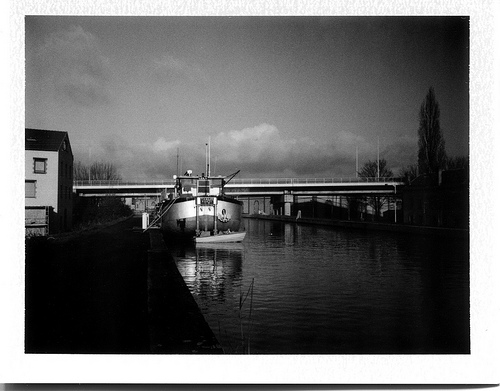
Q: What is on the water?
A: A boat.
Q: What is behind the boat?
A: A bridge.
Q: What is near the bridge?
A: A house.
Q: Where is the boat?
A: On the river.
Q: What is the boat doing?
A: It is docked.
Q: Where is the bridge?
A: Behind the boat.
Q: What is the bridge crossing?
A: A river.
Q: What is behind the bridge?
A: Ominous clouds.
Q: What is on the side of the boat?
A: The shore.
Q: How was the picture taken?
A: Black and white.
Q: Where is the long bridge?
A: Behind the ship.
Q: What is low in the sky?
A: Clouds.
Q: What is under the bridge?
A: Water.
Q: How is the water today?
A: Calm.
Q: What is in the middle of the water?
A: A canal.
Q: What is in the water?
A: Boat.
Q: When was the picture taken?
A: Daytime.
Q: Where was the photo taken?
A: Near the water.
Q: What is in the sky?
A: Clouds.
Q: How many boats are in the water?
A: One.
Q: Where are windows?
A: On a building.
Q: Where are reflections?
A: On the water.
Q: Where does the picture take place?
A: On the water.